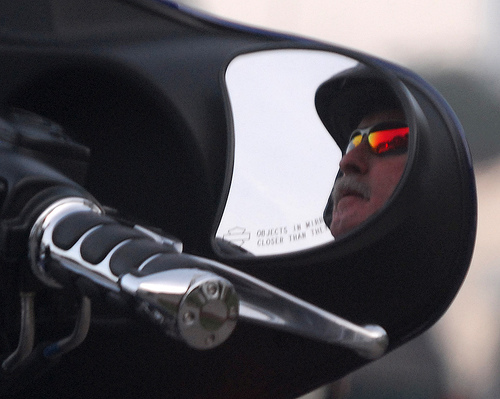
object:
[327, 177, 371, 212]
mustache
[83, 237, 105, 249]
black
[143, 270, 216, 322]
chrome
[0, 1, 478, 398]
motorcycle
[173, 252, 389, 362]
brakes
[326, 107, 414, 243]
man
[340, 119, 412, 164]
sunglasses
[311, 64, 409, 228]
helmet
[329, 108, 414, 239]
face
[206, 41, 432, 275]
mirror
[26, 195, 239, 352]
handle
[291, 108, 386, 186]
part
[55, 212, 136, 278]
part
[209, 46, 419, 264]
edge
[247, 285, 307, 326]
part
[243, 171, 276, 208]
part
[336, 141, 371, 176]
nose